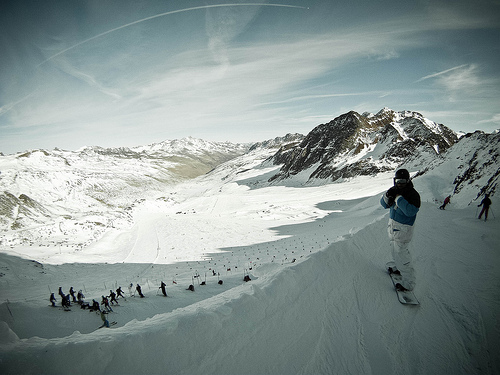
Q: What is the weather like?
A: It is cloudy.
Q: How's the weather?
A: It is cloudy.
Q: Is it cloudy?
A: Yes, it is cloudy.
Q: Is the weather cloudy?
A: Yes, it is cloudy.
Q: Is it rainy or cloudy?
A: It is cloudy.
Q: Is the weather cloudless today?
A: No, it is cloudy.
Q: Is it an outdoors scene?
A: Yes, it is outdoors.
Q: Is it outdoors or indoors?
A: It is outdoors.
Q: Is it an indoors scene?
A: No, it is outdoors.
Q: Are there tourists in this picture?
A: No, there are no tourists.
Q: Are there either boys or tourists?
A: No, there are no tourists or boys.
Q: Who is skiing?
A: The skier is skiing.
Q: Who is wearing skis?
A: The skier is wearing skis.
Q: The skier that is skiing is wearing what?
A: The skier is wearing skis.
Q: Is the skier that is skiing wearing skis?
A: Yes, the skier is wearing skis.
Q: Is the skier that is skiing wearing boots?
A: No, the skier is wearing skis.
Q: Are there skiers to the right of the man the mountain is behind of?
A: Yes, there is a skier to the right of the man.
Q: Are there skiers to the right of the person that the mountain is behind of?
A: Yes, there is a skier to the right of the man.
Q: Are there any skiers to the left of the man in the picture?
A: No, the skier is to the right of the man.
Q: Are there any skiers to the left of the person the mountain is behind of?
A: No, the skier is to the right of the man.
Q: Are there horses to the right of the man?
A: No, there is a skier to the right of the man.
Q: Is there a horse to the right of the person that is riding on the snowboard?
A: No, there is a skier to the right of the man.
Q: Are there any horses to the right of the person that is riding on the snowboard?
A: No, there is a skier to the right of the man.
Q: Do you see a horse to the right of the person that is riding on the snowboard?
A: No, there is a skier to the right of the man.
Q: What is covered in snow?
A: The mountain is covered in snow.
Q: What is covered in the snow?
A: The mountain is covered in snow.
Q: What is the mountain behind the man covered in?
A: The mountain is covered in snow.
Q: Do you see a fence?
A: No, there are no fences.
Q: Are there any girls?
A: No, there are no girls.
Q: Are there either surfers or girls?
A: No, there are no girls or surfers.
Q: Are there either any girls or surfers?
A: No, there are no girls or surfers.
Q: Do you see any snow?
A: Yes, there is snow.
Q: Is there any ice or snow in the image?
A: Yes, there is snow.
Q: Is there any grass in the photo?
A: No, there is no grass.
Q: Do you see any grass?
A: No, there is no grass.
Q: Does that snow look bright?
A: Yes, the snow is bright.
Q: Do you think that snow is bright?
A: Yes, the snow is bright.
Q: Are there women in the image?
A: No, there are no women.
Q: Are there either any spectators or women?
A: No, there are no women or spectators.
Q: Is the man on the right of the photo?
A: Yes, the man is on the right of the image.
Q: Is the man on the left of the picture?
A: No, the man is on the right of the image.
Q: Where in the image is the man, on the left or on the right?
A: The man is on the right of the image.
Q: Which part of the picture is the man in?
A: The man is on the right of the image.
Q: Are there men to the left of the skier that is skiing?
A: Yes, there is a man to the left of the skier.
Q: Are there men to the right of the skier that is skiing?
A: No, the man is to the left of the skier.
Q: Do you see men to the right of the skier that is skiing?
A: No, the man is to the left of the skier.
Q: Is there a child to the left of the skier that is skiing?
A: No, there is a man to the left of the skier.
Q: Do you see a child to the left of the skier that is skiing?
A: No, there is a man to the left of the skier.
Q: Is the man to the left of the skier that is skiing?
A: Yes, the man is to the left of the skier.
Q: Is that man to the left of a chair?
A: No, the man is to the left of the skier.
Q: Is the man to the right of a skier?
A: No, the man is to the left of a skier.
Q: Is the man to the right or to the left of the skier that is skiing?
A: The man is to the left of the skier.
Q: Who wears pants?
A: The man wears pants.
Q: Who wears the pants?
A: The man wears pants.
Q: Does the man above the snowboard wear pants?
A: Yes, the man wears pants.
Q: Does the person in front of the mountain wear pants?
A: Yes, the man wears pants.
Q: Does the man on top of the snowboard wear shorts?
A: No, the man wears pants.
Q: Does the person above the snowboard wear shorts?
A: No, the man wears pants.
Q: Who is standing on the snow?
A: The man is standing on the snow.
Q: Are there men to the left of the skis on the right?
A: Yes, there is a man to the left of the skis.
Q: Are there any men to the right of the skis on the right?
A: No, the man is to the left of the skis.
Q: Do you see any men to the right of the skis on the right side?
A: No, the man is to the left of the skis.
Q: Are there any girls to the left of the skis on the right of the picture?
A: No, there is a man to the left of the skis.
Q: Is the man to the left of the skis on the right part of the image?
A: Yes, the man is to the left of the skis.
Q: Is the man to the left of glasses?
A: No, the man is to the left of the skis.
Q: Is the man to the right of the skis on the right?
A: No, the man is to the left of the skis.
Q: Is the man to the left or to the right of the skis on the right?
A: The man is to the left of the skis.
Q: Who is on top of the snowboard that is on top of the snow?
A: The man is on top of the snowboard.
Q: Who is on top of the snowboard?
A: The man is on top of the snowboard.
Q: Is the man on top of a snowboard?
A: Yes, the man is on top of a snowboard.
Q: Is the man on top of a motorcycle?
A: No, the man is on top of a snowboard.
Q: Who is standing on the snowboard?
A: The man is standing on the snow board.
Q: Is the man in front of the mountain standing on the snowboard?
A: Yes, the man is standing on the snowboard.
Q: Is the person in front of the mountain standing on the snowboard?
A: Yes, the man is standing on the snowboard.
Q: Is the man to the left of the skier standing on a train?
A: No, the man is standing on the snowboard.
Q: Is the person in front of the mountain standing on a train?
A: No, the man is standing on the snowboard.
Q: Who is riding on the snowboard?
A: The man is riding on the snowboard.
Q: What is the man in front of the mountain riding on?
A: The man is riding on the snow board.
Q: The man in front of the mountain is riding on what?
A: The man is riding on the snow board.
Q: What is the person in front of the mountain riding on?
A: The man is riding on the snow board.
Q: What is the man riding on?
A: The man is riding on the snow board.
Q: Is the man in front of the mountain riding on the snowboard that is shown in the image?
A: Yes, the man is riding on the snowboard.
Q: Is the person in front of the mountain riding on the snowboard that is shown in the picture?
A: Yes, the man is riding on the snowboard.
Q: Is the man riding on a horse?
A: No, the man is riding on the snowboard.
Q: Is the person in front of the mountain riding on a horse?
A: No, the man is riding on the snowboard.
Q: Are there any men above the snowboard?
A: Yes, there is a man above the snowboard.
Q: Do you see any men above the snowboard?
A: Yes, there is a man above the snowboard.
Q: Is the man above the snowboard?
A: Yes, the man is above the snowboard.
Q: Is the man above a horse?
A: No, the man is above the snowboard.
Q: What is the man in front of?
A: The man is in front of the mountain.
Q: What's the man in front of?
A: The man is in front of the mountain.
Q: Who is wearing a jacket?
A: The man is wearing a jacket.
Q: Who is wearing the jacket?
A: The man is wearing a jacket.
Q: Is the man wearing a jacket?
A: Yes, the man is wearing a jacket.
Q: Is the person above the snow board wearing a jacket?
A: Yes, the man is wearing a jacket.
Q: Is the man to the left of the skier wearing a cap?
A: No, the man is wearing a jacket.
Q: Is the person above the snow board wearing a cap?
A: No, the man is wearing a jacket.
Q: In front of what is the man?
A: The man is in front of the mountain.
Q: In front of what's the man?
A: The man is in front of the mountain.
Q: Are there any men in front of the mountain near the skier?
A: Yes, there is a man in front of the mountain.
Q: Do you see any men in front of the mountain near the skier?
A: Yes, there is a man in front of the mountain.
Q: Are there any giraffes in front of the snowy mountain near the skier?
A: No, there is a man in front of the mountain.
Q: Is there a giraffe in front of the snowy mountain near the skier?
A: No, there is a man in front of the mountain.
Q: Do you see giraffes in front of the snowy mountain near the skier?
A: No, there is a man in front of the mountain.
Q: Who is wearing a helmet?
A: The man is wearing a helmet.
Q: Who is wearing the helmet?
A: The man is wearing a helmet.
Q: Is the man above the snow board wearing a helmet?
A: Yes, the man is wearing a helmet.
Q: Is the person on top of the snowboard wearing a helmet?
A: Yes, the man is wearing a helmet.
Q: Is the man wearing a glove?
A: No, the man is wearing a helmet.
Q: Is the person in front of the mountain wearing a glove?
A: No, the man is wearing a helmet.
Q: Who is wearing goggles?
A: The man is wearing goggles.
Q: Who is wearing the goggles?
A: The man is wearing goggles.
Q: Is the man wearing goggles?
A: Yes, the man is wearing goggles.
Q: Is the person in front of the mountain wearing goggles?
A: Yes, the man is wearing goggles.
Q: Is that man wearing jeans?
A: No, the man is wearing goggles.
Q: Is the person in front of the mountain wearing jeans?
A: No, the man is wearing goggles.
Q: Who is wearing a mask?
A: The man is wearing a mask.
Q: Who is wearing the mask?
A: The man is wearing a mask.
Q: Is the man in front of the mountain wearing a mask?
A: Yes, the man is wearing a mask.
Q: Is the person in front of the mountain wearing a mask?
A: Yes, the man is wearing a mask.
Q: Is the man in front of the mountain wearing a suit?
A: No, the man is wearing a mask.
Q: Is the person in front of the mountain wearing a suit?
A: No, the man is wearing a mask.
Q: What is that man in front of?
A: The man is in front of the mountain.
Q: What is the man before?
A: The man is in front of the mountain.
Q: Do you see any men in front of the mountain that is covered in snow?
A: Yes, there is a man in front of the mountain.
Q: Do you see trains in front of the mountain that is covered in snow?
A: No, there is a man in front of the mountain.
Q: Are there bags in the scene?
A: No, there are no bags.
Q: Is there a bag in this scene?
A: No, there are no bags.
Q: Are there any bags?
A: No, there are no bags.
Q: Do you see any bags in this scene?
A: No, there are no bags.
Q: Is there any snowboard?
A: Yes, there is a snowboard.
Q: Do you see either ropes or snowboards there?
A: Yes, there is a snowboard.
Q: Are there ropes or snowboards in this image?
A: Yes, there is a snowboard.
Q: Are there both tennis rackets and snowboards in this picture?
A: No, there is a snowboard but no rackets.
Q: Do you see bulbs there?
A: No, there are no bulbs.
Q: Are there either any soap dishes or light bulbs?
A: No, there are no light bulbs or soap dishes.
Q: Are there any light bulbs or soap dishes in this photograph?
A: No, there are no light bulbs or soap dishes.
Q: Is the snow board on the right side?
A: Yes, the snow board is on the right of the image.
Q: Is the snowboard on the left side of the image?
A: No, the snowboard is on the right of the image.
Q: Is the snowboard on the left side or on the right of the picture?
A: The snowboard is on the right of the image.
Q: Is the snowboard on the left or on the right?
A: The snowboard is on the right of the image.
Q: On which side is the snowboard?
A: The snowboard is on the right of the image.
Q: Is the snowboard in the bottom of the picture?
A: Yes, the snowboard is in the bottom of the image.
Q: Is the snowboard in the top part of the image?
A: No, the snowboard is in the bottom of the image.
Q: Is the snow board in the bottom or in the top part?
A: The snow board is in the bottom of the image.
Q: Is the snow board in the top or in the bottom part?
A: The snow board is in the bottom of the image.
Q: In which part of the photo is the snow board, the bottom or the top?
A: The snow board is in the bottom of the image.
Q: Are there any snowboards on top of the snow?
A: Yes, there is a snowboard on top of the snow.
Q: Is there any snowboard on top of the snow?
A: Yes, there is a snowboard on top of the snow.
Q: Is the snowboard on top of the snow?
A: Yes, the snowboard is on top of the snow.